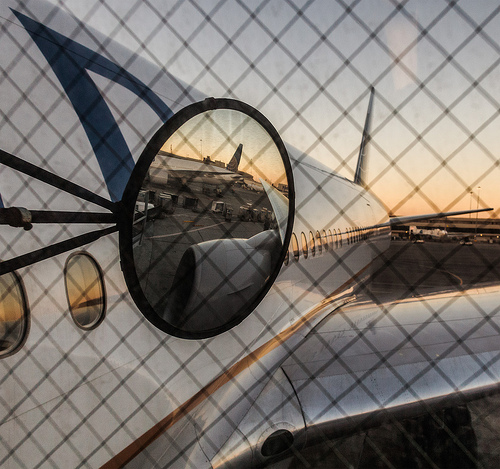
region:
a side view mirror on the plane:
[3, 83, 296, 344]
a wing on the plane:
[190, 272, 494, 466]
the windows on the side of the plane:
[288, 216, 395, 258]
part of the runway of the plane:
[389, 238, 499, 293]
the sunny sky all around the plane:
[41, 0, 499, 235]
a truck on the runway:
[409, 223, 449, 240]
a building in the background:
[424, 207, 499, 232]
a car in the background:
[463, 227, 495, 242]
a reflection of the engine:
[156, 240, 281, 347]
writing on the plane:
[15, 10, 176, 190]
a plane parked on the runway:
[3, 0, 495, 464]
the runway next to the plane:
[395, 232, 498, 460]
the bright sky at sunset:
[87, 2, 499, 224]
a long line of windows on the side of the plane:
[289, 210, 402, 253]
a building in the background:
[392, 210, 499, 240]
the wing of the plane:
[241, 288, 496, 454]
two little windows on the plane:
[0, 255, 112, 353]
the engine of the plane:
[167, 223, 269, 336]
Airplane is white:
[8, 0, 499, 467]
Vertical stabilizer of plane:
[336, 68, 394, 187]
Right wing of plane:
[298, 271, 499, 448]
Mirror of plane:
[104, 89, 316, 348]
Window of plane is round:
[53, 247, 118, 339]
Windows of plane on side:
[289, 221, 372, 263]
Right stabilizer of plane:
[388, 191, 498, 238]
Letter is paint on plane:
[13, 5, 188, 205]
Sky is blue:
[185, 5, 498, 105]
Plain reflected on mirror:
[149, 136, 280, 219]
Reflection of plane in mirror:
[116, 143, 261, 322]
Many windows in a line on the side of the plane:
[252, 227, 387, 257]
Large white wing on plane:
[231, 281, 463, 406]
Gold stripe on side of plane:
[143, 330, 323, 361]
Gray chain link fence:
[274, 295, 466, 461]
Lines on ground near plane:
[395, 243, 474, 295]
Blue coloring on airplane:
[69, 122, 134, 191]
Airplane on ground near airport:
[69, 179, 411, 429]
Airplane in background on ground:
[401, 213, 449, 263]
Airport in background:
[360, 173, 470, 285]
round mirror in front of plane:
[30, 90, 370, 370]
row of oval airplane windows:
[0, 206, 420, 346]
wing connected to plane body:
[146, 275, 416, 456]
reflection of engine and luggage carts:
[130, 178, 275, 319]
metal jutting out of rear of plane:
[345, 65, 491, 240]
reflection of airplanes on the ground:
[120, 87, 305, 212]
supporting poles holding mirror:
[0, 140, 155, 335]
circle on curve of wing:
[215, 405, 315, 457]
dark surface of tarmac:
[391, 235, 488, 290]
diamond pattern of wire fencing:
[63, 45, 453, 396]